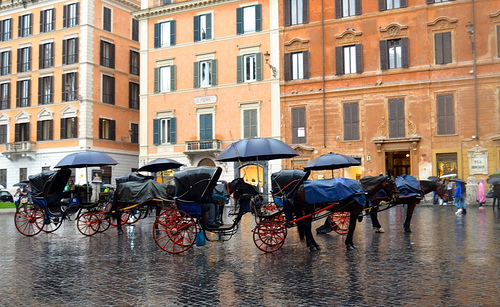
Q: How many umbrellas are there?
A: 4.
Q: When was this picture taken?
A: Daytime.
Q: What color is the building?
A: Brown.